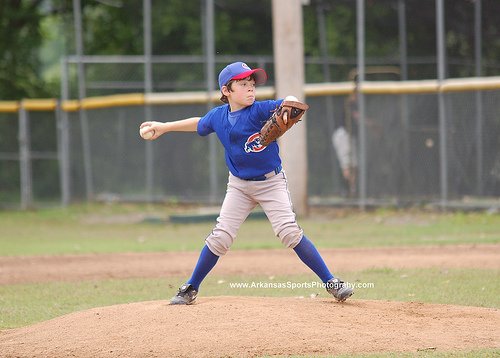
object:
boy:
[138, 60, 355, 305]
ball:
[138, 125, 154, 140]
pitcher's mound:
[1, 295, 499, 357]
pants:
[204, 169, 302, 258]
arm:
[167, 112, 214, 140]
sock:
[292, 236, 333, 284]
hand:
[138, 120, 164, 141]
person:
[330, 121, 358, 197]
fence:
[0, 0, 499, 209]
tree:
[1, 0, 99, 99]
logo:
[242, 133, 268, 154]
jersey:
[197, 99, 282, 179]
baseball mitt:
[258, 99, 310, 144]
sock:
[186, 244, 219, 292]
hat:
[218, 61, 267, 93]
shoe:
[169, 282, 197, 305]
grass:
[0, 270, 500, 329]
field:
[1, 209, 499, 357]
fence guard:
[1, 74, 499, 113]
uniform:
[185, 97, 332, 288]